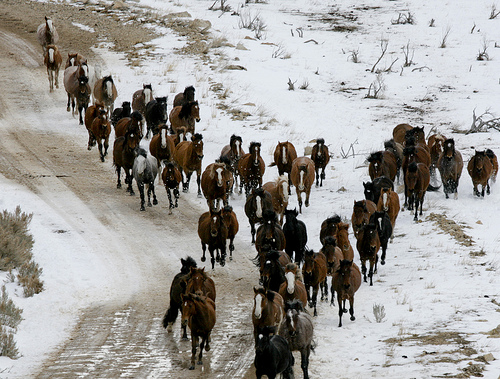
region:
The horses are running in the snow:
[15, 35, 495, 357]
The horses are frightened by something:
[27, 37, 478, 347]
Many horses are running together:
[37, 41, 482, 351]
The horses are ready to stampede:
[18, 17, 493, 363]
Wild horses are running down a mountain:
[21, 30, 472, 371]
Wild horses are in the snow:
[21, 25, 482, 356]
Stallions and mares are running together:
[20, 46, 486, 366]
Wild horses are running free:
[35, 27, 461, 358]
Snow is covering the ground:
[35, 13, 490, 369]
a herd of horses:
[20, 17, 496, 377]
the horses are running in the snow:
[20, 10, 497, 361]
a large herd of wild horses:
[21, 6, 496, 366]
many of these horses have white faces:
[27, 18, 308, 373]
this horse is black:
[242, 325, 314, 377]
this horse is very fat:
[283, 149, 323, 210]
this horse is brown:
[172, 289, 221, 372]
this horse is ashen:
[120, 146, 165, 214]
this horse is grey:
[127, 146, 167, 213]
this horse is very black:
[278, 201, 318, 263]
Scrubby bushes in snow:
[0, 204, 45, 364]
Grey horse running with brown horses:
[129, 147, 164, 212]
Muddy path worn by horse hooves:
[34, 310, 271, 377]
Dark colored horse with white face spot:
[248, 314, 291, 377]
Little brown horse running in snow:
[159, 162, 186, 212]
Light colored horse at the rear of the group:
[33, 13, 64, 48]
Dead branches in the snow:
[350, 39, 417, 96]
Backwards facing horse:
[151, 253, 200, 335]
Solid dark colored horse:
[278, 205, 308, 260]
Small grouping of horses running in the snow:
[357, 115, 498, 192]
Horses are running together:
[30, 38, 491, 368]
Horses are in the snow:
[33, 27, 483, 374]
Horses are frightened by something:
[30, 35, 482, 340]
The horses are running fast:
[18, 50, 483, 362]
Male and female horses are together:
[30, 41, 485, 349]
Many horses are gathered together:
[41, 30, 471, 361]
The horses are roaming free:
[36, 55, 482, 365]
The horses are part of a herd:
[60, 72, 481, 352]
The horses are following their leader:
[47, 78, 468, 348]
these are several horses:
[143, 140, 394, 377]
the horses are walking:
[165, 155, 388, 377]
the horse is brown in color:
[268, 294, 281, 316]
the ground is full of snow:
[296, 78, 350, 133]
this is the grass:
[0, 213, 30, 266]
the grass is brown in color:
[0, 213, 31, 265]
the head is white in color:
[251, 291, 261, 318]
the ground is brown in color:
[107, 306, 152, 371]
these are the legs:
[191, 330, 214, 361]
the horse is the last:
[34, 10, 51, 45]